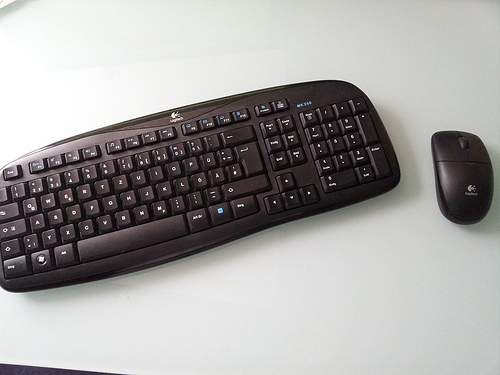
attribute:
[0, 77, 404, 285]
keyboard — black, cordless, wireless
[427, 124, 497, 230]
mouse — black, optical, present, cordless, wireless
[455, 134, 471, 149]
wheel — scrolling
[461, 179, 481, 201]
logo — white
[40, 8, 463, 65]
table — white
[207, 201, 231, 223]
key — blue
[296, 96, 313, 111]
letters — blue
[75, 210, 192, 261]
spacebar — black